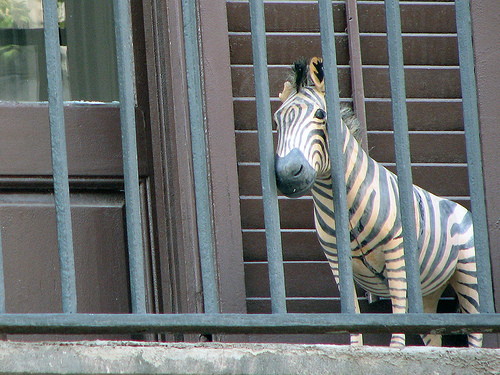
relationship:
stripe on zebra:
[366, 166, 407, 246] [272, 54, 482, 350]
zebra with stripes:
[272, 52, 492, 361] [273, 85, 482, 350]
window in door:
[2, 1, 141, 104] [4, 0, 168, 340]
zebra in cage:
[272, 54, 482, 350] [182, 0, 499, 346]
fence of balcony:
[1, 0, 496, 335] [0, 340, 497, 373]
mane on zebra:
[267, 58, 319, 108] [272, 52, 492, 361]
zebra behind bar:
[272, 54, 482, 350] [248, 0, 287, 312]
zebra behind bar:
[272, 54, 482, 350] [317, 0, 355, 312]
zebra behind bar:
[272, 54, 482, 350] [383, 2, 425, 314]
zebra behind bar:
[272, 54, 482, 350] [455, 0, 496, 309]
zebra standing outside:
[272, 52, 492, 361] [2, 2, 482, 369]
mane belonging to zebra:
[288, 58, 309, 94] [272, 54, 482, 350]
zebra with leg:
[272, 54, 482, 350] [382, 237, 408, 347]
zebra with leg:
[272, 54, 482, 350] [453, 249, 483, 348]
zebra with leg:
[272, 54, 482, 350] [415, 281, 447, 345]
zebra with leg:
[272, 54, 482, 350] [330, 258, 362, 342]